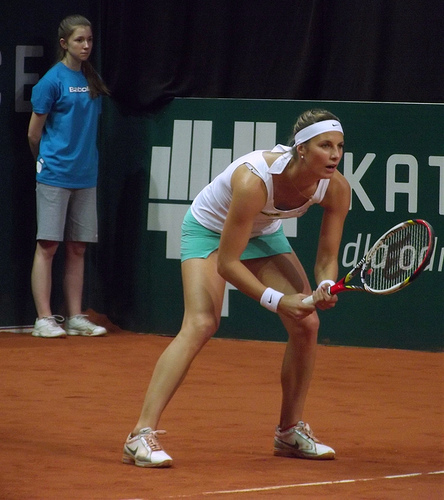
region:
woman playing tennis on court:
[76, 96, 436, 456]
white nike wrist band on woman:
[261, 286, 287, 312]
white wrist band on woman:
[320, 273, 332, 289]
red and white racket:
[307, 210, 440, 324]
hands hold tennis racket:
[257, 210, 437, 322]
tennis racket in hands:
[270, 212, 436, 326]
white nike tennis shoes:
[114, 413, 337, 478]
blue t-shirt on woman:
[23, 71, 109, 187]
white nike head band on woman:
[291, 113, 355, 149]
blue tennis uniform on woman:
[163, 219, 298, 260]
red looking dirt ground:
[0, 328, 443, 498]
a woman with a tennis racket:
[122, 107, 437, 498]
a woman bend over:
[121, 108, 356, 469]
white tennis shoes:
[120, 419, 336, 470]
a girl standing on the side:
[22, 14, 113, 340]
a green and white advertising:
[143, 96, 443, 347]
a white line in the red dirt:
[212, 465, 443, 497]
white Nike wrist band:
[254, 276, 286, 319]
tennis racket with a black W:
[303, 217, 436, 301]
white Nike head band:
[274, 116, 346, 180]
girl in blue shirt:
[28, 15, 102, 336]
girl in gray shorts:
[29, 11, 107, 337]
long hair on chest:
[49, 13, 107, 97]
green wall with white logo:
[106, 91, 441, 347]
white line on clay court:
[1, 330, 441, 498]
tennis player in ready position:
[121, 107, 435, 464]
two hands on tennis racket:
[290, 219, 432, 320]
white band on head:
[296, 107, 346, 179]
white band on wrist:
[257, 283, 311, 319]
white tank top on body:
[195, 150, 331, 233]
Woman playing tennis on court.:
[118, 106, 354, 468]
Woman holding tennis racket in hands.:
[291, 217, 436, 317]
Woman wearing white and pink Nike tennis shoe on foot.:
[118, 425, 173, 468]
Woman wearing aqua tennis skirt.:
[177, 205, 297, 265]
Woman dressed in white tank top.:
[187, 147, 329, 238]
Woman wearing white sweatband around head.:
[264, 117, 353, 174]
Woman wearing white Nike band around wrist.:
[256, 285, 287, 314]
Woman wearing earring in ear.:
[296, 151, 307, 163]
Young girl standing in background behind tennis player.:
[21, 12, 119, 341]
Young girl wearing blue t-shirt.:
[28, 57, 111, 192]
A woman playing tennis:
[122, 103, 436, 472]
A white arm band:
[257, 280, 284, 314]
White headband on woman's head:
[288, 118, 347, 179]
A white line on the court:
[169, 464, 443, 496]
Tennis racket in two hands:
[281, 212, 436, 326]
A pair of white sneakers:
[116, 415, 338, 473]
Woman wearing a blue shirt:
[23, 12, 109, 191]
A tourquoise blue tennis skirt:
[178, 206, 295, 262]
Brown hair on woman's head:
[52, 9, 111, 102]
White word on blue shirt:
[56, 77, 94, 97]